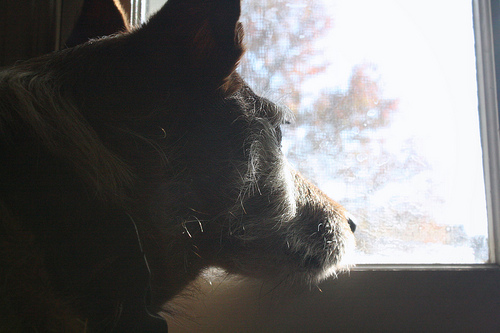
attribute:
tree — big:
[273, 13, 380, 134]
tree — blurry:
[235, 0, 394, 240]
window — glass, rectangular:
[140, 0, 492, 257]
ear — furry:
[132, 0, 249, 100]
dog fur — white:
[21, 16, 358, 303]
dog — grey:
[29, 20, 401, 300]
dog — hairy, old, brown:
[2, 1, 384, 330]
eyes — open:
[273, 109, 307, 173]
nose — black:
[347, 217, 356, 231]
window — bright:
[341, 70, 437, 180]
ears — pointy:
[0, 7, 265, 82]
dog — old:
[0, 12, 369, 308]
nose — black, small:
[347, 213, 357, 234]